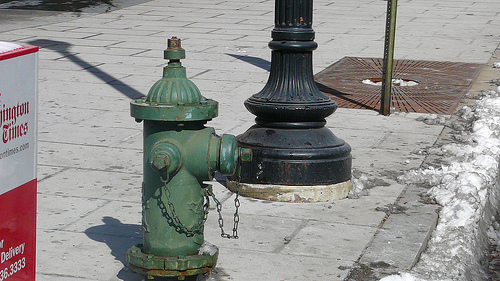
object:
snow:
[380, 89, 500, 281]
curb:
[405, 91, 498, 280]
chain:
[154, 162, 244, 239]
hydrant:
[124, 35, 254, 280]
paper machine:
[0, 42, 40, 281]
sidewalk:
[0, 0, 500, 280]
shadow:
[27, 35, 149, 102]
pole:
[228, 0, 352, 202]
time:
[2, 121, 32, 144]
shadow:
[84, 213, 149, 280]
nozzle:
[167, 36, 183, 51]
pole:
[379, 0, 397, 115]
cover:
[312, 55, 489, 116]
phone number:
[30, 235, 57, 259]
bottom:
[230, 125, 352, 185]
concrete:
[225, 175, 354, 203]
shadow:
[224, 51, 384, 113]